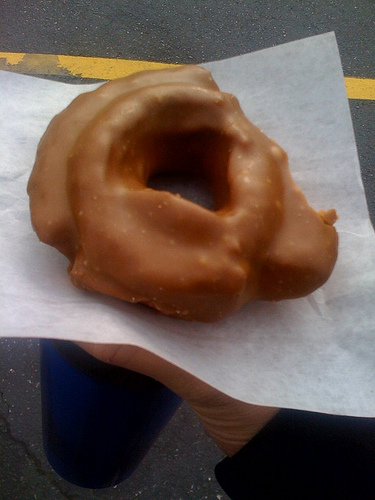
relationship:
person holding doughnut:
[31, 243, 374, 494] [25, 63, 353, 347]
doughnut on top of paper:
[25, 63, 353, 347] [4, 46, 373, 412]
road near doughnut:
[4, 0, 374, 134] [25, 63, 353, 347]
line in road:
[1, 49, 373, 109] [4, 0, 374, 134]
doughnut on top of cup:
[25, 63, 353, 347] [22, 320, 175, 494]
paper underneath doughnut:
[4, 46, 373, 412] [25, 63, 353, 347]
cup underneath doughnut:
[22, 320, 175, 494] [25, 63, 353, 347]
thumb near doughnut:
[56, 322, 282, 442] [25, 63, 353, 347]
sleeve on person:
[197, 383, 374, 497] [31, 243, 374, 494]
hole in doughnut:
[114, 121, 254, 218] [25, 63, 353, 347]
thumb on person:
[56, 322, 282, 442] [31, 243, 374, 494]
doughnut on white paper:
[25, 63, 353, 347] [4, 46, 373, 412]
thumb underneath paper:
[56, 322, 282, 442] [4, 46, 373, 412]